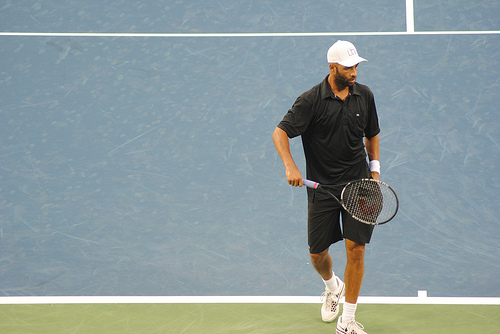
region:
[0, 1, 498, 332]
green and blue surface of tennis court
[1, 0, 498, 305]
white boundary on surface of tennis courts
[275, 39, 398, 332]
tennis player in black clothing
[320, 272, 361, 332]
white socks in sneakers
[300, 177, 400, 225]
racket with white string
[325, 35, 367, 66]
A white hat on a man's head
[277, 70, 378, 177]
A black shirt on a tennis player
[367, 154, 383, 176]
A white wristband on a man's arm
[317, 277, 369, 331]
White shoes on a man's feet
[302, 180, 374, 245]
Black shorts on a man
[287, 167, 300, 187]
A hand gripping a tennis racket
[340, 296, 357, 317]
A white sock on a man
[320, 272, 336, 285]
A white sock on a man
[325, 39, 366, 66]
A white cap on a man's head.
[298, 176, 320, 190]
Purple wrapped tennis racket handle with red stripe.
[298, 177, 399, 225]
A black and white tennis racket with purple wrapped handle.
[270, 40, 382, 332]
A man playing tennis in a white cap.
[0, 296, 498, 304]
White line separating the blue from green.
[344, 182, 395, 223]
White tennis racket strings.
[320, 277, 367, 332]
White shoes on a tennis player.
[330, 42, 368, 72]
a white hat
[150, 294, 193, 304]
a white line on the tennis court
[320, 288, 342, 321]
man is wearing shoes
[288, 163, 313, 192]
man holding a tennis racket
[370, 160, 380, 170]
a sweat band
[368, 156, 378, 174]
the band is white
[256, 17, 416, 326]
this is a man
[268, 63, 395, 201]
man wearing a black shirt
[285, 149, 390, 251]
man wearing black shorts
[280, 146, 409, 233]
this is a tennis racket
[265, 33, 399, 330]
man holding a tennis racket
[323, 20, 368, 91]
man wearing a white hat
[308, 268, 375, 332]
man wearing white shoes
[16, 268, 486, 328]
white lines on the court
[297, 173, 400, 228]
Black tennis racquet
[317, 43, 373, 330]
man standing on the field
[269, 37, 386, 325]
man standing holding a racket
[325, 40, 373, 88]
white cap on his head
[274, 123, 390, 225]
right hand holding the racket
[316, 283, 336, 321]
left white and red shoes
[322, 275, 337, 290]
White Sox left foot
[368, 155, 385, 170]
white and short left wrist